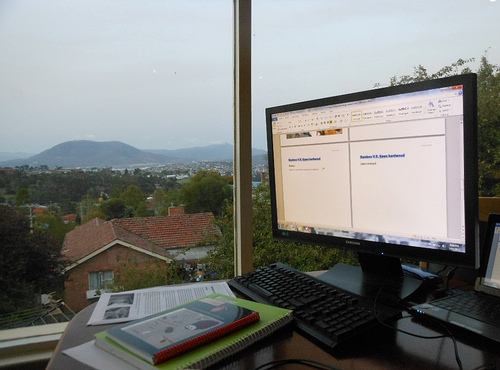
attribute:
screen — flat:
[266, 75, 477, 263]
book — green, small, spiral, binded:
[91, 294, 305, 369]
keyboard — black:
[229, 261, 401, 357]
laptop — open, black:
[412, 214, 499, 340]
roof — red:
[113, 221, 172, 262]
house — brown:
[56, 208, 222, 310]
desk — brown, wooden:
[52, 272, 500, 369]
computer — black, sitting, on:
[211, 59, 485, 354]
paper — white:
[87, 279, 235, 322]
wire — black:
[373, 287, 433, 346]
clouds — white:
[166, 46, 218, 78]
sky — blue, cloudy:
[1, 2, 496, 154]